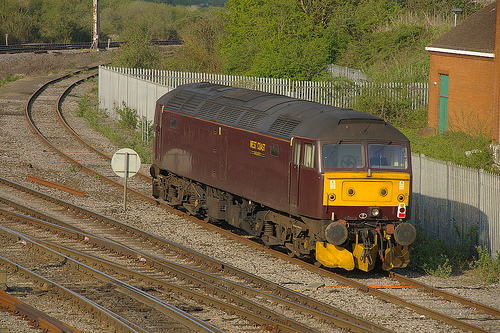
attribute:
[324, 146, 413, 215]
train — yellow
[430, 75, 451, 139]
door — green, darkgreen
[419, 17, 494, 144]
building — brown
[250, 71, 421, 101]
fence — wooden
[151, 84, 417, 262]
train — brown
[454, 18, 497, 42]
roof — drak, grey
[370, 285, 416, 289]
stripe — yellow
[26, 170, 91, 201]
pole — metal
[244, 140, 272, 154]
wrting — yellow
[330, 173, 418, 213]
trainengine — yellow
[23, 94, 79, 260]
train tracks — various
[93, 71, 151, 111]
picket fence — white, wooden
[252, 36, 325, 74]
trees — green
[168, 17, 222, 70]
shrubs — brown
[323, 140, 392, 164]
windshieldwipers — windshildwipers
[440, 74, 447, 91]
window — green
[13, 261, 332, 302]
traintracks — five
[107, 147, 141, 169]
roundsign — round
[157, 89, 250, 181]
traincar — burgundy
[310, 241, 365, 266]
trim — yellow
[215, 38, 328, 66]
bushes — green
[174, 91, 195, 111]
ehaustvent — silver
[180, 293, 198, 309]
railroard ties — wooden